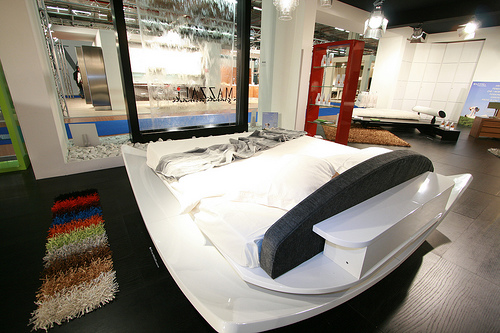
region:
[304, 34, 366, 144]
red bookshelf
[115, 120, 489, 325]
black and white bed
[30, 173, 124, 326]
multicolored stripe carpet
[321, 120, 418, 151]
brown square carpet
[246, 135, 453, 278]
black headboard leaning on a white shelf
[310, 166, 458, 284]
empty white shelf attached to a bed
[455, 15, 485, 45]
illuminated white light fixture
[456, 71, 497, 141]
blue and green poster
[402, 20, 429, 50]
metallic silver light fixture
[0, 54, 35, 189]
bottom right corner of a green bookshelf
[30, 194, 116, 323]
Multicolored area rug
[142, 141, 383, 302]
White Modernistic design of bed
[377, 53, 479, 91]
white privacy screen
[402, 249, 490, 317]
brown laminate floor tile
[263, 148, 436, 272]
Black head board against white bed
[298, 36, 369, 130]
red shelving unit with glass shelves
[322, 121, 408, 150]
brown area rug on brown floor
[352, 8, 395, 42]
silver ceiling light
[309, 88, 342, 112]
glass bottles on glass shelve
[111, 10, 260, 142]
black framed window sign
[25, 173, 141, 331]
the rug has many colors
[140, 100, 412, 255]
the bed is white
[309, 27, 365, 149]
the shelf is red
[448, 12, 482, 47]
the light is on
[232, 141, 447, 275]
the board is black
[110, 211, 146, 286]
the ground is black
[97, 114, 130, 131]
the floor is blue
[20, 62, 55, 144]
the wall is white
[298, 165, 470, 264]
the shelf is white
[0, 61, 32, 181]
the shelf is green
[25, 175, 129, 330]
the rug is on the floor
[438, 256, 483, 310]
the floor is brown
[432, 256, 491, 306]
the floor is made of wood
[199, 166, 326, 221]
the bed is white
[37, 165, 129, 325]
the rug is colorful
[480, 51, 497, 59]
the wall is white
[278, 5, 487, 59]
the lights are on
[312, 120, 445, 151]
the rug is brown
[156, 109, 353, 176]
the blanket is gray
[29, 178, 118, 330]
A small carpet with many colors.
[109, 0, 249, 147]
A window with a black frame.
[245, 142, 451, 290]
A grey headboard for a bed.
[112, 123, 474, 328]
A large bed with a white base.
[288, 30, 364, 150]
A red shelf with several bottles on it.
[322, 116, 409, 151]
A brown rug on the floor.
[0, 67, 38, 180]
A lime green shelf in the corner.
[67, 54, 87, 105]
A person standing behind metal shelves.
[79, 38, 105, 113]
A set of metal shelves.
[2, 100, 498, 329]
A brown hardwood floor.